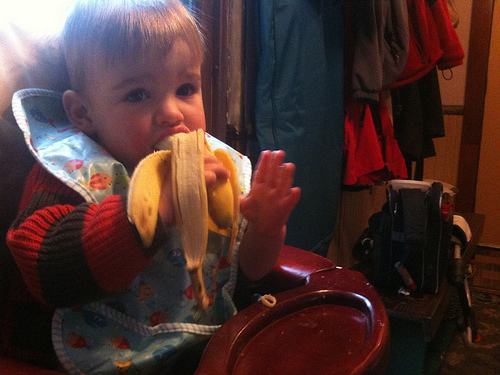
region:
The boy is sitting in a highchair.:
[2, 0, 398, 372]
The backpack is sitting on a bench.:
[335, 167, 495, 372]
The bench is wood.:
[321, 166, 493, 371]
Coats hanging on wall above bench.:
[235, 0, 496, 370]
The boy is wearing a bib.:
[0, 1, 306, 373]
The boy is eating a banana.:
[1, 1, 304, 372]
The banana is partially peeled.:
[0, 2, 314, 374]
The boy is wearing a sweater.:
[0, 0, 312, 373]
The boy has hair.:
[0, 1, 252, 317]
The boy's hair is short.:
[1, 0, 245, 325]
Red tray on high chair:
[202, 262, 389, 374]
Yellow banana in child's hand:
[124, 132, 238, 300]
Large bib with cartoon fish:
[13, 86, 255, 371]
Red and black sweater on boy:
[12, 168, 164, 303]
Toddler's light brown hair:
[59, 1, 212, 79]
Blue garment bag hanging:
[254, 0, 341, 247]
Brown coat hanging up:
[356, 0, 416, 97]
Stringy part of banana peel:
[259, 294, 275, 304]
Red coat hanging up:
[401, 0, 461, 91]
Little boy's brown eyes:
[126, 85, 204, 100]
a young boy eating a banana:
[53, 7, 242, 279]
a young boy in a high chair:
[65, 7, 375, 372]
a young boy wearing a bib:
[48, 24, 272, 281]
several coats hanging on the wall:
[251, 7, 471, 190]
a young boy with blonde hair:
[43, 12, 229, 138]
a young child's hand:
[236, 128, 319, 262]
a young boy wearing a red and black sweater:
[18, 12, 210, 299]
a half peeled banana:
[126, 108, 238, 285]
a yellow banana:
[93, 103, 248, 285]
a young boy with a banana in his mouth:
[91, 17, 226, 229]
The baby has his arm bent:
[6, 160, 132, 315]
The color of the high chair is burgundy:
[2, 230, 401, 372]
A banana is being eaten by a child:
[125, 118, 242, 311]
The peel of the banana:
[168, 130, 236, 309]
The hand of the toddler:
[228, 147, 303, 240]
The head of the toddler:
[55, 0, 215, 172]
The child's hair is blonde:
[51, 1, 230, 87]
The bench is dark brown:
[345, 197, 490, 374]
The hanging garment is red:
[343, 94, 410, 190]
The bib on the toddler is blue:
[0, 87, 253, 374]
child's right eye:
[122, 87, 151, 101]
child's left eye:
[177, 83, 195, 95]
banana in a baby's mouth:
[127, 128, 240, 300]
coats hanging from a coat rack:
[259, 5, 464, 73]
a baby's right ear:
[60, 90, 95, 132]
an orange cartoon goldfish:
[82, 172, 109, 189]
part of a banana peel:
[255, 295, 275, 305]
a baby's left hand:
[241, 149, 300, 229]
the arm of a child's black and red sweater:
[21, 200, 131, 305]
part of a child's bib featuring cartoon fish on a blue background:
[130, 279, 190, 331]